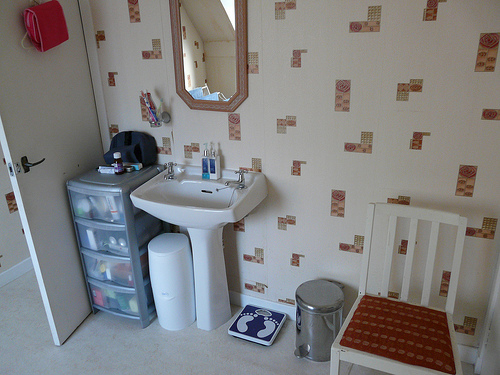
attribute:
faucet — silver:
[220, 168, 244, 198]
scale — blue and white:
[228, 300, 286, 347]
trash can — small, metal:
[288, 274, 348, 369]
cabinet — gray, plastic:
[66, 160, 163, 328]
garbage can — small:
[293, 279, 345, 362]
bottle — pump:
[209, 143, 225, 178]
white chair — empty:
[329, 202, 468, 373]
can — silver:
[290, 278, 344, 361]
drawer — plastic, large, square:
[65, 183, 133, 224]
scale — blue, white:
[227, 302, 288, 350]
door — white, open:
[3, 40, 102, 350]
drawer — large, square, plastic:
[65, 181, 143, 325]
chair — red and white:
[345, 192, 457, 371]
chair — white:
[328, 197, 471, 374]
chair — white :
[321, 195, 464, 373]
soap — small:
[207, 141, 220, 180]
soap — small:
[199, 142, 211, 179]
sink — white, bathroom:
[131, 161, 269, 329]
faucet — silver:
[226, 169, 247, 193]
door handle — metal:
[22, 153, 46, 171]